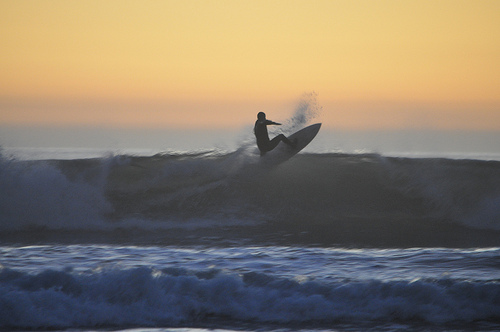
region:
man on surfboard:
[238, 105, 330, 176]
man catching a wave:
[241, 107, 326, 184]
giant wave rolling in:
[0, 146, 499, 247]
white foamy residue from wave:
[0, 258, 499, 327]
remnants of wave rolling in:
[3, 231, 498, 318]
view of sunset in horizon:
[1, 67, 499, 158]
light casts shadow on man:
[248, 110, 296, 154]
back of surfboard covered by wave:
[223, 107, 328, 177]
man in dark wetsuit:
[252, 107, 301, 159]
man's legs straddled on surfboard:
[238, 105, 303, 162]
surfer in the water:
[251, 108, 335, 169]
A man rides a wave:
[249, 101, 327, 179]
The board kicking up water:
[278, 86, 339, 136]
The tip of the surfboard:
[296, 116, 331, 151]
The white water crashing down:
[8, 262, 493, 329]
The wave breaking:
[356, 154, 498, 229]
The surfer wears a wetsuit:
[251, 112, 298, 163]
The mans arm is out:
[265, 116, 286, 129]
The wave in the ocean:
[22, 148, 244, 239]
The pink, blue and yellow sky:
[348, 51, 472, 146]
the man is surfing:
[75, 54, 453, 238]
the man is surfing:
[164, 57, 409, 327]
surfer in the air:
[195, 81, 340, 196]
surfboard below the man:
[300, 100, 330, 150]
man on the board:
[236, 107, 281, 157]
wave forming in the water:
[341, 138, 412, 208]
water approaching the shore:
[161, 250, 262, 314]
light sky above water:
[123, 37, 192, 84]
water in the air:
[289, 90, 326, 124]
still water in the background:
[52, 136, 85, 160]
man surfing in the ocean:
[235, 100, 319, 172]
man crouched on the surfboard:
[207, 107, 321, 184]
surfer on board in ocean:
[217, 90, 325, 185]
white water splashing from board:
[291, 95, 319, 128]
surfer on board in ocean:
[245, 105, 292, 152]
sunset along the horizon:
[345, 40, 473, 147]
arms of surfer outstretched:
[258, 117, 288, 131]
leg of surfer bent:
[273, 127, 298, 157]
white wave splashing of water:
[6, 280, 91, 320]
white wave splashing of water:
[137, 267, 205, 323]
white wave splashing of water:
[219, 273, 287, 327]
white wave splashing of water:
[283, 280, 355, 316]